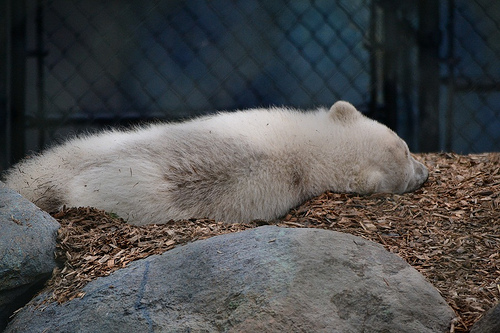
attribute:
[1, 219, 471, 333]
rock — large, gray, big, grey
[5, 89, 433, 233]
dog — white, furry, sleep, sleeping, laying down, grey, nose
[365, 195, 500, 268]
chips — wood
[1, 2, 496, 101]
fence — metal, chain link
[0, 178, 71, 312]
boulder — gray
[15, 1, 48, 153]
pole — metal